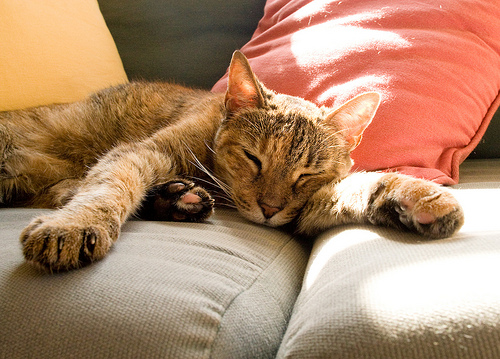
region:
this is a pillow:
[264, 8, 486, 79]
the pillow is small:
[260, 5, 477, 84]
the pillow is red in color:
[251, 46, 290, 66]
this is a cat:
[3, 49, 463, 264]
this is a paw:
[23, 213, 104, 257]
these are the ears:
[201, 34, 376, 139]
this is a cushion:
[268, 262, 422, 335]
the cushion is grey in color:
[204, 272, 319, 326]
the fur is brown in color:
[140, 93, 212, 133]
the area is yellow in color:
[26, 28, 66, 64]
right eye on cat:
[233, 138, 272, 173]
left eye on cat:
[296, 167, 318, 177]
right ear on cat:
[230, 77, 272, 109]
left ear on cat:
[334, 95, 421, 165]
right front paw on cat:
[44, 212, 116, 265]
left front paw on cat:
[394, 161, 464, 231]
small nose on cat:
[261, 191, 283, 216]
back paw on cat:
[167, 182, 215, 229]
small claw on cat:
[86, 227, 103, 249]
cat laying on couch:
[190, 95, 417, 298]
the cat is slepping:
[32, 83, 477, 300]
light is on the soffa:
[352, 254, 488, 357]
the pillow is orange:
[261, 1, 466, 172]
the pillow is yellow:
[13, 15, 118, 85]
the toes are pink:
[182, 179, 202, 219]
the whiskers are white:
[173, 145, 251, 203]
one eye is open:
[227, 133, 269, 175]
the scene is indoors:
[4, 9, 494, 355]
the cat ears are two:
[221, 58, 391, 140]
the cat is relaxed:
[15, 94, 452, 276]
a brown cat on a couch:
[11, 43, 492, 350]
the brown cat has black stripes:
[1, 45, 460, 292]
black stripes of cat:
[286, 108, 313, 152]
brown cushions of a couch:
[1, 146, 496, 351]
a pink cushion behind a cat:
[230, 0, 495, 170]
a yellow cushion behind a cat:
[0, 0, 130, 120]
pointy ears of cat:
[218, 37, 388, 134]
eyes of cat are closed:
[235, 136, 326, 186]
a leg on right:
[320, 160, 466, 241]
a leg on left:
[12, 140, 154, 276]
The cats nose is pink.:
[255, 198, 281, 220]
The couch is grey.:
[135, 251, 262, 357]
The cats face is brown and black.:
[218, 50, 386, 230]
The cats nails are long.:
[15, 217, 103, 270]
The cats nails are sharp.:
[19, 225, 103, 274]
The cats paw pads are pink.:
[158, 176, 218, 223]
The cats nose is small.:
[256, 198, 280, 222]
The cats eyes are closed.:
[229, 138, 336, 185]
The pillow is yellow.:
[8, 7, 85, 68]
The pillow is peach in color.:
[290, 13, 421, 83]